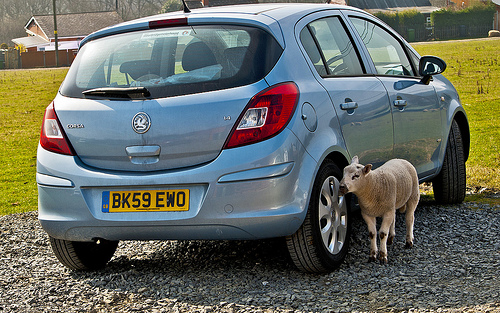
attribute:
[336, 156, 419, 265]
lamb — standing, white, small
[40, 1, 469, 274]
car — parked, blue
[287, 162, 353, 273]
wheel — rubber, black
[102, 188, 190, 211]
license plate — blue, yellow, narrow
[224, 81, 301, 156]
taillight — red, clear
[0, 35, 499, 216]
field — green, covered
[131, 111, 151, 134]
logo — circular, silver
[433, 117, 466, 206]
front wheel — black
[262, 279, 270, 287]
rock — small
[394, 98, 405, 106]
handle — blue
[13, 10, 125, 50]
house — brick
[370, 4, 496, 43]
shrub — tall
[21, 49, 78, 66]
fence — board, red, rusty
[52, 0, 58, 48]
pole — electrical, wooden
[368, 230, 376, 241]
smudge — dark